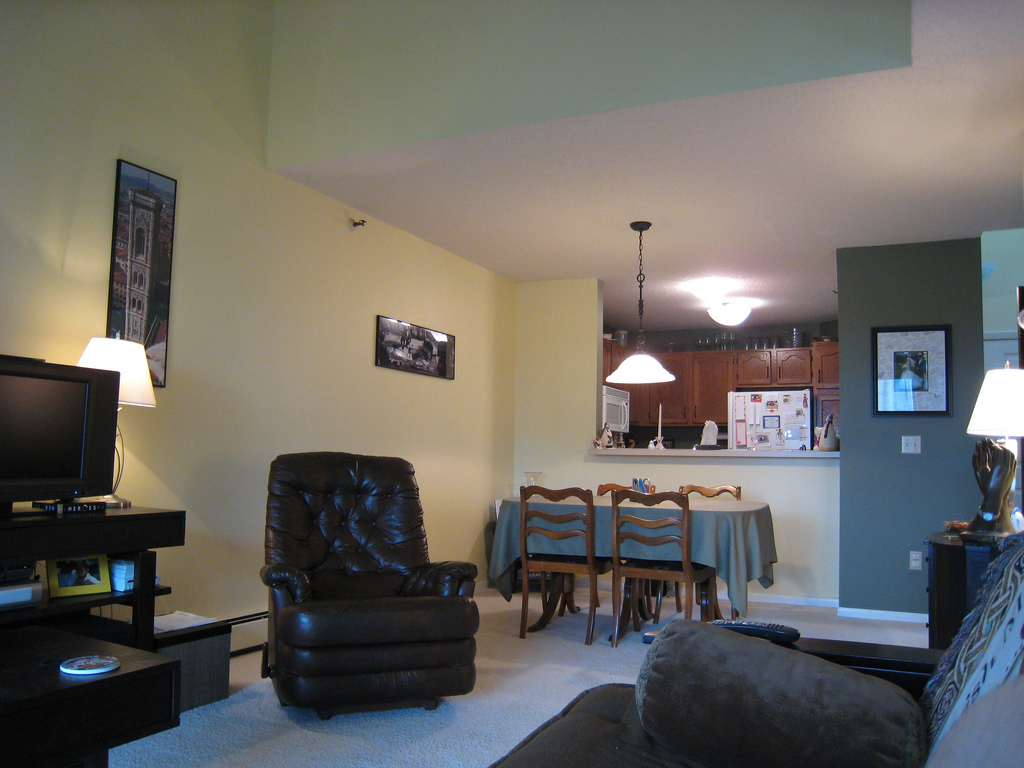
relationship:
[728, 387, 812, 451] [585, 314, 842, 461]
white fridge in kitchen